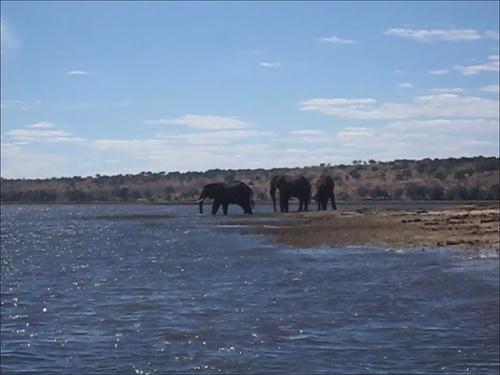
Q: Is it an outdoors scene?
A: Yes, it is outdoors.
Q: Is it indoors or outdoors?
A: It is outdoors.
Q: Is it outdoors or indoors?
A: It is outdoors.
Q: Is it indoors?
A: No, it is outdoors.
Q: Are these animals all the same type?
A: Yes, all the animals are elephants.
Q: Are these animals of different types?
A: No, all the animals are elephants.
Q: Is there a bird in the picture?
A: No, there are no birds.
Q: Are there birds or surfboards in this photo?
A: No, there are no birds or surfboards.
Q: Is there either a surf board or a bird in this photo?
A: No, there are no birds or surfboards.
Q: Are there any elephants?
A: Yes, there is an elephant.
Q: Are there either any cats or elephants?
A: Yes, there is an elephant.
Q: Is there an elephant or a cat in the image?
A: Yes, there is an elephant.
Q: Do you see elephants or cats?
A: Yes, there is an elephant.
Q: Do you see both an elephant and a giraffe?
A: No, there is an elephant but no giraffes.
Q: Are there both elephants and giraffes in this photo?
A: No, there is an elephant but no giraffes.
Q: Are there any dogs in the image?
A: No, there are no dogs.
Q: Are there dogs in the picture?
A: No, there are no dogs.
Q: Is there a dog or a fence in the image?
A: No, there are no dogs or fences.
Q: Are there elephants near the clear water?
A: Yes, there is an elephant near the water.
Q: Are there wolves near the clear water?
A: No, there is an elephant near the water.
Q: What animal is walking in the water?
A: The animal is an elephant.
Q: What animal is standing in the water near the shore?
A: The elephant is standing in the water.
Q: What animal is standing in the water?
A: The elephant is standing in the water.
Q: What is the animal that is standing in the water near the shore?
A: The animal is an elephant.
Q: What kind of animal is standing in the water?
A: The animal is an elephant.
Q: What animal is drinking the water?
A: The elephant is drinking the water.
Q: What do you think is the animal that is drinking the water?
A: The animal is an elephant.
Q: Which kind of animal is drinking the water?
A: The animal is an elephant.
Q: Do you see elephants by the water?
A: Yes, there is an elephant by the water.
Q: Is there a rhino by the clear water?
A: No, there is an elephant by the water.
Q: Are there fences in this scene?
A: No, there are no fences.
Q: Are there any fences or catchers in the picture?
A: No, there are no fences or catchers.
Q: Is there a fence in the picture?
A: No, there are no fences.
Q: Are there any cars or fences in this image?
A: No, there are no fences or cars.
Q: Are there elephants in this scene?
A: Yes, there is an elephant.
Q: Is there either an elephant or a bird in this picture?
A: Yes, there is an elephant.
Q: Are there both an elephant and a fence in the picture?
A: No, there is an elephant but no fences.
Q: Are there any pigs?
A: No, there are no pigs.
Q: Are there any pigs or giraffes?
A: No, there are no pigs or giraffes.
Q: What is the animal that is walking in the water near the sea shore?
A: The animal is an elephant.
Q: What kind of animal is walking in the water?
A: The animal is an elephant.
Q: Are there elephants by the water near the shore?
A: Yes, there is an elephant by the water.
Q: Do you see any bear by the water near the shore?
A: No, there is an elephant by the water.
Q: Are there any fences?
A: No, there are no fences.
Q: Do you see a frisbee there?
A: No, there are no frisbees.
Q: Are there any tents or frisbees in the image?
A: No, there are no frisbees or tents.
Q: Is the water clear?
A: Yes, the water is clear.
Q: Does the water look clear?
A: Yes, the water is clear.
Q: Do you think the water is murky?
A: No, the water is clear.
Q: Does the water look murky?
A: No, the water is clear.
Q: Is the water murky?
A: No, the water is clear.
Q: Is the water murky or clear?
A: The water is clear.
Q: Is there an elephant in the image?
A: Yes, there is an elephant.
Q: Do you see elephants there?
A: Yes, there is an elephant.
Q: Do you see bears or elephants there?
A: Yes, there is an elephant.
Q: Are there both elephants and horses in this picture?
A: No, there is an elephant but no horses.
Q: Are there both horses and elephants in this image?
A: No, there is an elephant but no horses.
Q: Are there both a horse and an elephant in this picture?
A: No, there is an elephant but no horses.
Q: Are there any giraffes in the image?
A: No, there are no giraffes.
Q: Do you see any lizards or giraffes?
A: No, there are no giraffes or lizards.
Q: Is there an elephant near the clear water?
A: Yes, there is an elephant near the water.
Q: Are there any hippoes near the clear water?
A: No, there is an elephant near the water.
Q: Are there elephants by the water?
A: Yes, there is an elephant by the water.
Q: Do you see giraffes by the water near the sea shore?
A: No, there is an elephant by the water.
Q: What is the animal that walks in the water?
A: The animal is an elephant.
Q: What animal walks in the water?
A: The animal is an elephant.